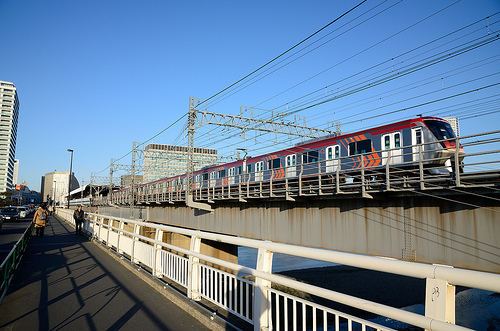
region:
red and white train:
[233, 138, 398, 188]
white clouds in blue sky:
[9, 16, 57, 56]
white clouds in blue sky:
[50, 13, 117, 67]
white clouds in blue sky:
[23, 62, 88, 104]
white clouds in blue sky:
[32, 98, 76, 132]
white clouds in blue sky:
[63, 71, 135, 128]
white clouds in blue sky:
[112, 62, 159, 132]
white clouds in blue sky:
[119, 15, 177, 87]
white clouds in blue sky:
[156, 35, 231, 89]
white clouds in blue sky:
[303, 19, 348, 71]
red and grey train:
[95, 105, 473, 200]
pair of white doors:
[378, 130, 404, 164]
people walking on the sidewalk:
[28, 200, 86, 236]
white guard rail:
[107, 214, 218, 292]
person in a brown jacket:
[29, 204, 50, 233]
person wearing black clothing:
[74, 203, 85, 235]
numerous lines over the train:
[98, 9, 491, 181]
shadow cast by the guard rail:
[28, 250, 157, 326]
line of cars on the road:
[2, 200, 37, 234]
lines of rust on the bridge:
[252, 198, 454, 240]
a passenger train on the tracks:
[145, 116, 466, 203]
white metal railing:
[134, 214, 327, 329]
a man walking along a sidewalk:
[65, 202, 105, 244]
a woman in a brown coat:
[22, 199, 55, 234]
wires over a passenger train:
[197, 67, 334, 134]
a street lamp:
[54, 138, 93, 210]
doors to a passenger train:
[379, 131, 406, 164]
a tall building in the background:
[2, 79, 29, 199]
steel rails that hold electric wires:
[172, 90, 219, 220]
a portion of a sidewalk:
[21, 254, 112, 329]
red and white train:
[271, 126, 443, 201]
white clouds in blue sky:
[24, 43, 81, 90]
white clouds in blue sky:
[28, 105, 85, 143]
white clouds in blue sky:
[102, 88, 138, 120]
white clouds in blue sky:
[39, 38, 129, 93]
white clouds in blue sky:
[142, 20, 184, 47]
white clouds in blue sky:
[181, 5, 229, 51]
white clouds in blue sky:
[283, 53, 355, 98]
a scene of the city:
[21, 63, 474, 313]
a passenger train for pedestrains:
[108, 123, 460, 202]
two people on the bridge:
[30, 189, 97, 246]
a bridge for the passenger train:
[68, 199, 476, 316]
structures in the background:
[1, 75, 43, 201]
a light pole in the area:
[63, 138, 75, 209]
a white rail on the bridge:
[101, 221, 344, 303]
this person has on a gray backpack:
[32, 208, 54, 233]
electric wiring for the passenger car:
[134, 46, 474, 156]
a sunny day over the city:
[10, 43, 470, 313]